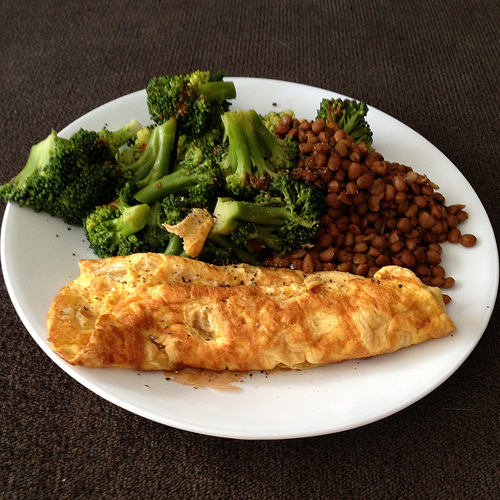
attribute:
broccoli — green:
[79, 199, 156, 250]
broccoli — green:
[205, 182, 322, 263]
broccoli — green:
[80, 194, 152, 243]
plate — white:
[2, 74, 484, 442]